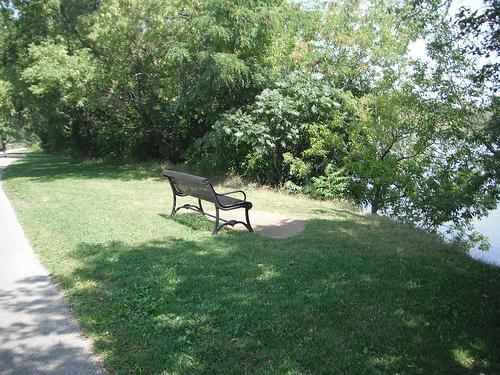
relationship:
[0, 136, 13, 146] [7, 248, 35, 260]
person on sidewalk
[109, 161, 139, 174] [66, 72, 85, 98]
shadow of tree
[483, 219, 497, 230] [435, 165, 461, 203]
water behind tree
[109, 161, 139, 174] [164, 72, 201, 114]
shadow of trees